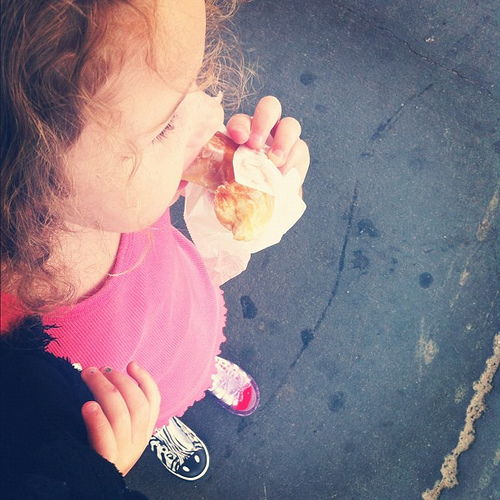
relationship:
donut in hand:
[185, 127, 268, 228] [186, 101, 313, 257]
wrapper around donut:
[179, 125, 310, 290] [185, 127, 268, 228]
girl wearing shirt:
[1, 0, 311, 499] [2, 207, 229, 430]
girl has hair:
[1, 0, 311, 499] [1, 0, 256, 323]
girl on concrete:
[1, 0, 311, 499] [123, 1, 499, 499]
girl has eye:
[1, 0, 311, 499] [149, 112, 175, 146]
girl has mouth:
[1, 0, 311, 499] [175, 123, 230, 194]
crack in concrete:
[332, 1, 499, 104] [123, 1, 499, 499]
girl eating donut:
[1, 0, 311, 499] [185, 127, 268, 228]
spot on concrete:
[299, 66, 317, 87] [123, 1, 499, 499]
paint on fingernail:
[105, 367, 112, 373] [99, 363, 118, 378]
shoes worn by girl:
[148, 412, 210, 480] [1, 0, 311, 499]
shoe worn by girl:
[210, 353, 261, 419] [1, 0, 311, 499]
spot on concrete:
[314, 101, 328, 114] [123, 1, 499, 499]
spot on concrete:
[238, 293, 259, 321] [123, 1, 499, 499]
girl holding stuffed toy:
[1, 0, 311, 499] [0, 312, 151, 500]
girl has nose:
[1, 0, 311, 499] [195, 88, 226, 150]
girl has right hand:
[1, 0, 311, 499] [80, 360, 163, 483]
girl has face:
[1, 0, 311, 499] [63, 3, 228, 239]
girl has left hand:
[1, 0, 311, 499] [186, 101, 313, 257]